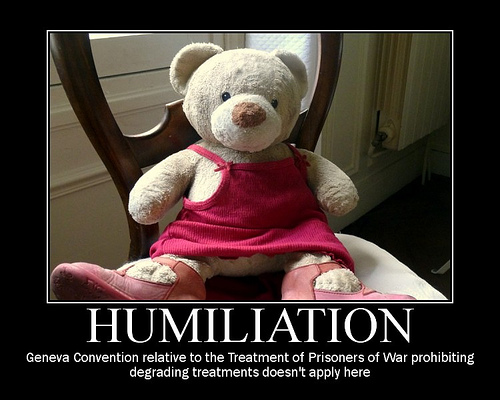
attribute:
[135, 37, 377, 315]
teddy bear — white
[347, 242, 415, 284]
chair — brown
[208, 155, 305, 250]
dress — pink, red, tiny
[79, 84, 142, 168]
chair back — wood, brown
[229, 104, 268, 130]
nose — brown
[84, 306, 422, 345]
letters — white, large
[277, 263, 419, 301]
shoe — pink, red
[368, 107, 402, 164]
wall radiator — white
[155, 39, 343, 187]
bear — tan, stuffed, sitting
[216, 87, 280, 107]
eyes — black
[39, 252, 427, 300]
shoes — red, pink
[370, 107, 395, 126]
radiator — white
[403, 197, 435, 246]
floor — dark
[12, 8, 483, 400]
poster — motivational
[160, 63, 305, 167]
doll — sitting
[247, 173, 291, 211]
cloth — pink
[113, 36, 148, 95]
door — white